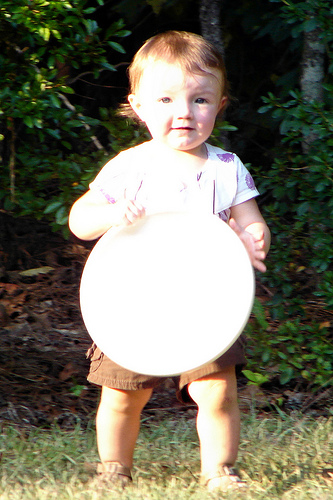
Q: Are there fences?
A: No, there are no fences.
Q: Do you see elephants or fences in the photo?
A: No, there are no fences or elephants.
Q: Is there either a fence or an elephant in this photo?
A: No, there are no fences or elephants.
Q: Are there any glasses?
A: No, there are no glasses.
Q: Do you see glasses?
A: No, there are no glasses.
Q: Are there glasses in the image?
A: No, there are no glasses.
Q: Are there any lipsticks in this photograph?
A: No, there are no lipsticks.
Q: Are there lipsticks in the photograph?
A: No, there are no lipsticks.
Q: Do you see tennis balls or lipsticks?
A: No, there are no lipsticks or tennis balls.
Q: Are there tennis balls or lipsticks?
A: No, there are no lipsticks or tennis balls.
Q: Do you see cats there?
A: No, there are no cats.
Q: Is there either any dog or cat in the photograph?
A: No, there are no cats or dogs.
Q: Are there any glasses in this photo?
A: No, there are no glasses.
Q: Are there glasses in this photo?
A: No, there are no glasses.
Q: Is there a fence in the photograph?
A: No, there are no fences.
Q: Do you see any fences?
A: No, there are no fences.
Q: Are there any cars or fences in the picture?
A: No, there are no fences or cars.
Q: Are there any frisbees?
A: Yes, there is a frisbee.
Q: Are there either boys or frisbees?
A: Yes, there is a frisbee.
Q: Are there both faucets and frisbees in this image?
A: No, there is a frisbee but no faucets.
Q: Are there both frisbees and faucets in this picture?
A: No, there is a frisbee but no faucets.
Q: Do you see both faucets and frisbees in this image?
A: No, there is a frisbee but no faucets.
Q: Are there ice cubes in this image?
A: No, there are no ice cubes.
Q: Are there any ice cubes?
A: No, there are no ice cubes.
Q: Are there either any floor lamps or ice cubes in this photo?
A: No, there are no ice cubes or floor lamps.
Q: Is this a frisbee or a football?
A: This is a frisbee.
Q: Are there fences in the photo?
A: No, there are no fences.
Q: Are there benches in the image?
A: No, there are no benches.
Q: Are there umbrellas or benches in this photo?
A: No, there are no benches or umbrellas.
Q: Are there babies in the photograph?
A: Yes, there is a baby.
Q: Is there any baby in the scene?
A: Yes, there is a baby.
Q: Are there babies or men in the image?
A: Yes, there is a baby.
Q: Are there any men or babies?
A: Yes, there is a baby.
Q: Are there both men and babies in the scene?
A: No, there is a baby but no men.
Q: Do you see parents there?
A: No, there are no parents.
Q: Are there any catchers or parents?
A: No, there are no parents or catchers.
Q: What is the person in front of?
A: The baby is in front of the leaves.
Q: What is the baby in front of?
A: The baby is in front of the leaves.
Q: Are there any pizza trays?
A: No, there are no pizza trays.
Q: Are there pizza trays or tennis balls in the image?
A: No, there are no pizza trays or tennis balls.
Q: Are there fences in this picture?
A: No, there are no fences.